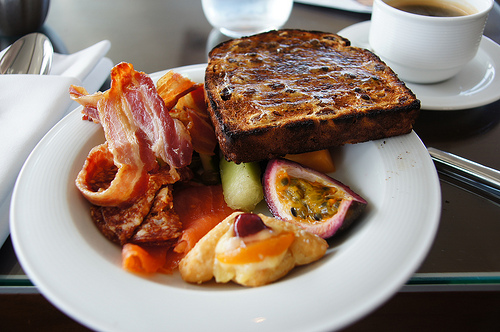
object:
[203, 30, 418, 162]
topping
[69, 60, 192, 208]
bacon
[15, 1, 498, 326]
breakfast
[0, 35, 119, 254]
napkin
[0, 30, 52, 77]
spoon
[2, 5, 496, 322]
table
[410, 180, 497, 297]
glass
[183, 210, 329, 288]
crepe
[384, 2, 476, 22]
coffee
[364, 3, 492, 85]
mug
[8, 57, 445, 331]
plate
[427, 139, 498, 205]
utensil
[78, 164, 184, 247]
salami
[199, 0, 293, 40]
water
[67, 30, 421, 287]
eating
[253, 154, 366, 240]
fruit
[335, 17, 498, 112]
plate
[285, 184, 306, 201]
seeds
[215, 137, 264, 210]
celery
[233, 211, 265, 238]
cherry